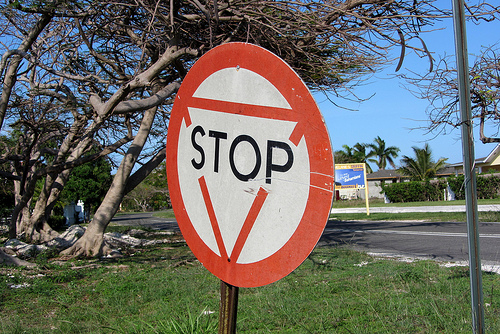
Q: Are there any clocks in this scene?
A: No, there are no clocks.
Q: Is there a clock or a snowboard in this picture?
A: No, there are no clocks or snowboards.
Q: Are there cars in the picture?
A: No, there are no cars.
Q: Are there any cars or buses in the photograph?
A: No, there are no cars or buses.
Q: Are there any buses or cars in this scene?
A: No, there are no cars or buses.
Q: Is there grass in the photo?
A: Yes, there is grass.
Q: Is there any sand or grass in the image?
A: Yes, there is grass.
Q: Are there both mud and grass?
A: No, there is grass but no mud.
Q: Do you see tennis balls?
A: No, there are no tennis balls.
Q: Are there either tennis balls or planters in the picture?
A: No, there are no tennis balls or planters.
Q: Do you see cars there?
A: No, there are no cars.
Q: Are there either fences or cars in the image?
A: No, there are no cars or fences.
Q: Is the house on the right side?
A: Yes, the house is on the right of the image.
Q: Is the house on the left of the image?
A: No, the house is on the right of the image.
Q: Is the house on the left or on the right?
A: The house is on the right of the image.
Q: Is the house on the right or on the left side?
A: The house is on the right of the image.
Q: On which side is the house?
A: The house is on the right of the image.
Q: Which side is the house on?
A: The house is on the right of the image.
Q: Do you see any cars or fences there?
A: No, there are no cars or fences.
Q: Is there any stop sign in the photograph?
A: Yes, there is a stop sign.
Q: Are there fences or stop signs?
A: Yes, there is a stop sign.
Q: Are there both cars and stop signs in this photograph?
A: No, there is a stop sign but no cars.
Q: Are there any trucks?
A: No, there are no trucks.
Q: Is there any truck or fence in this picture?
A: No, there are no trucks or fences.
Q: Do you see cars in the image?
A: No, there are no cars.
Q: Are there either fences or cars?
A: No, there are no cars or fences.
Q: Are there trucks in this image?
A: No, there are no trucks.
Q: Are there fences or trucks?
A: No, there are no trucks or fences.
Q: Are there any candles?
A: No, there are no candles.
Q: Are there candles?
A: No, there are no candles.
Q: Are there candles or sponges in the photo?
A: No, there are no candles or sponges.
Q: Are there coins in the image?
A: No, there are no coins.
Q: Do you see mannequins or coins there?
A: No, there are no coins or mannequins.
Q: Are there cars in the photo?
A: No, there are no cars.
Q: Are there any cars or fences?
A: No, there are no cars or fences.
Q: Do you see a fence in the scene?
A: No, there are no fences.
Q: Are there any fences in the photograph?
A: No, there are no fences.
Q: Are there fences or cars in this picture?
A: No, there are no fences or cars.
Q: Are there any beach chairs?
A: No, there are no beach chairs.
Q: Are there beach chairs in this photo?
A: No, there are no beach chairs.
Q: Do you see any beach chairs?
A: No, there are no beach chairs.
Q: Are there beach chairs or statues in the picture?
A: No, there are no beach chairs or statues.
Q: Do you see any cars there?
A: No, there are no cars.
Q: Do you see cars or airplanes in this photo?
A: No, there are no cars or airplanes.